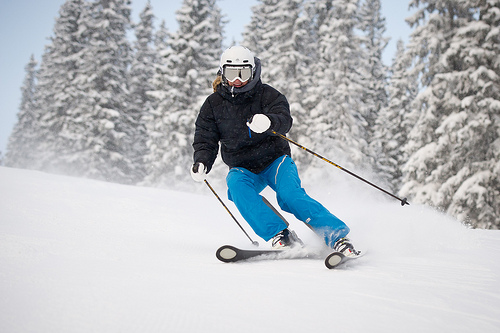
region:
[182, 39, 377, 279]
person skiing down slope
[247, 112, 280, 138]
person's left white glove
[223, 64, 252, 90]
smiling face of a skiier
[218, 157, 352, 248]
bright blue ski pants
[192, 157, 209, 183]
right white gloved hand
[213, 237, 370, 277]
set of skiis on the snow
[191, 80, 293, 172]
black ski jacket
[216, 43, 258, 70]
white colored skiing helmet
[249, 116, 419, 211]
black and yellow colored ski pole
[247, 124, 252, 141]
blue colored tassel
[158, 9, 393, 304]
the man is skiing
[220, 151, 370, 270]
the pants are blue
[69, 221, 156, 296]
the snow is white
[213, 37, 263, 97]
the helmet is white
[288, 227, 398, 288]
the shoes are white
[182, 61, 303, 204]
the jacket is black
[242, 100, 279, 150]
the glove is white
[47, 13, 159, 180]
the trees have snow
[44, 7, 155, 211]
the trees are tall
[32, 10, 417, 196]
there are many trees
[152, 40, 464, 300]
A person is skiing on snow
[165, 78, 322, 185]
The person skiing is wearing a black coat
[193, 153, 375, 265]
The person skiing is wearing blue pants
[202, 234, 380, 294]
Ski boards are black underneath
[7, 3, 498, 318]
Photo was taken in the daytime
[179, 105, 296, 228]
Person is wearing white gloves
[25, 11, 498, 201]
Trees are in the background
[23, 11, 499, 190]
Trees are snow covered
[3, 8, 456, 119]
The sky is clear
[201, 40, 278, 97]
Person is wearing a white helmet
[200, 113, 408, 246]
Ski poles in the man's hands.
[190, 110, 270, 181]
White gloves on the skier's hands.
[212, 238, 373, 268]
Snow skis on the man's feet.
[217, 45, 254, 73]
White helmet on the man's head.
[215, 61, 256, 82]
Googles on the skier's face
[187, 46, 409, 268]
Man skiing on a snowy mountain.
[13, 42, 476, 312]
Skier skiing at a ski resort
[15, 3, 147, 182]
Green tree covered with snow.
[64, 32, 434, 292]
Skier wearing a black winter coat.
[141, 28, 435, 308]
Man skiing down on snow.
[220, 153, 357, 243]
blue ski pants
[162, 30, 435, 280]
person in a black jacket skiing downhill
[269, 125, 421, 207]
black and orange ski pole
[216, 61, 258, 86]
white and black ski googles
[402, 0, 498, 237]
snow covered evergreen tree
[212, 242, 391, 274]
pair of black and white skis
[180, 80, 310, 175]
puffy black ski jacket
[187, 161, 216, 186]
white gloved hand holding a ski pole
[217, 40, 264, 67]
white ski cap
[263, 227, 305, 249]
black ski boot